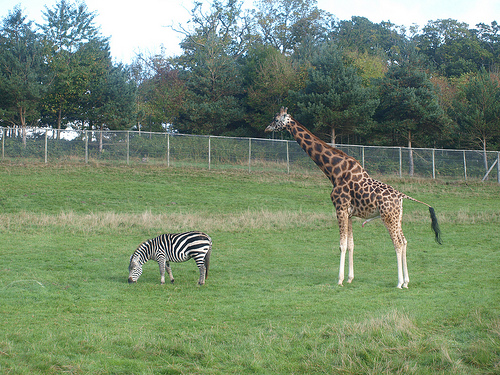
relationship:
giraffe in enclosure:
[263, 106, 443, 289] [0, 127, 499, 373]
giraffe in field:
[263, 106, 443, 289] [1, 163, 500, 373]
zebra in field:
[127, 230, 213, 285] [1, 163, 500, 373]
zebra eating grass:
[127, 230, 213, 285] [2, 159, 499, 371]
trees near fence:
[0, 0, 499, 169] [1, 125, 500, 180]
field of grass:
[1, 163, 500, 373] [2, 159, 499, 371]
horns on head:
[278, 106, 290, 117] [263, 103, 293, 135]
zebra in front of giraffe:
[127, 230, 213, 285] [263, 106, 443, 289]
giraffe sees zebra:
[263, 106, 443, 289] [127, 230, 213, 285]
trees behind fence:
[0, 0, 499, 169] [1, 125, 500, 180]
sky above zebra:
[1, 1, 499, 73] [127, 230, 213, 285]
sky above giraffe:
[1, 1, 499, 73] [263, 106, 443, 289]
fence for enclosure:
[1, 125, 500, 180] [0, 127, 499, 373]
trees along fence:
[0, 0, 499, 169] [1, 125, 500, 180]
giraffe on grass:
[263, 106, 443, 289] [2, 159, 499, 371]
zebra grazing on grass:
[127, 230, 213, 285] [2, 159, 499, 371]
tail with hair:
[402, 192, 445, 243] [426, 205, 444, 244]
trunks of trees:
[3, 106, 110, 155] [0, 0, 499, 169]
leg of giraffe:
[336, 212, 347, 287] [263, 106, 443, 289]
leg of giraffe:
[346, 219, 354, 282] [263, 106, 443, 289]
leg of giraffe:
[387, 223, 402, 289] [263, 106, 443, 289]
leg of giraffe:
[399, 223, 410, 288] [263, 106, 443, 289]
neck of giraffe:
[289, 118, 352, 182] [263, 106, 443, 289]